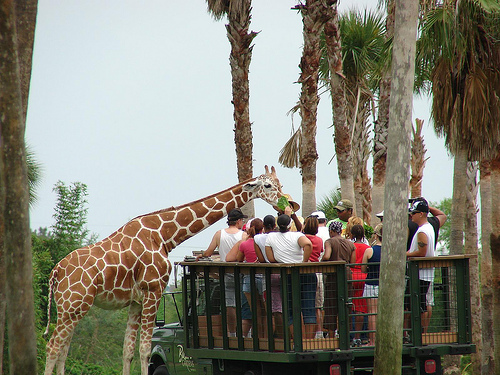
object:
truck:
[149, 288, 476, 373]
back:
[182, 262, 476, 363]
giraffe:
[41, 166, 286, 375]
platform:
[186, 333, 479, 361]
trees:
[214, 2, 262, 373]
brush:
[24, 226, 83, 331]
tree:
[2, 0, 35, 373]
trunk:
[6, 162, 36, 375]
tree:
[343, 5, 385, 235]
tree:
[437, 2, 493, 253]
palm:
[304, 7, 394, 92]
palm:
[416, 2, 499, 92]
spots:
[97, 259, 107, 271]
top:
[248, 164, 279, 181]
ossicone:
[271, 166, 276, 175]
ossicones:
[264, 165, 269, 175]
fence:
[184, 260, 470, 350]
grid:
[301, 268, 458, 350]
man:
[408, 200, 437, 347]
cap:
[408, 198, 429, 212]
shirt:
[265, 231, 307, 264]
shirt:
[216, 226, 245, 261]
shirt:
[254, 233, 274, 263]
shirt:
[410, 224, 437, 283]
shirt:
[312, 226, 335, 260]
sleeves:
[264, 234, 272, 247]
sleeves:
[418, 227, 429, 238]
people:
[194, 208, 248, 340]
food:
[277, 196, 294, 215]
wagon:
[183, 255, 473, 363]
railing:
[176, 253, 477, 270]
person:
[285, 205, 303, 233]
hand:
[285, 206, 292, 217]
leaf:
[275, 196, 288, 211]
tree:
[380, 2, 415, 374]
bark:
[377, 0, 416, 372]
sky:
[29, 0, 459, 280]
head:
[248, 165, 292, 214]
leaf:
[279, 128, 302, 170]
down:
[2, 361, 499, 375]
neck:
[154, 179, 258, 244]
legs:
[137, 289, 159, 373]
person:
[300, 210, 331, 343]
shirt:
[305, 235, 325, 263]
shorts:
[220, 268, 251, 307]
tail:
[43, 271, 53, 336]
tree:
[51, 176, 93, 253]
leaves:
[79, 199, 87, 204]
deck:
[199, 315, 457, 350]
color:
[415, 199, 426, 208]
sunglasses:
[411, 211, 423, 216]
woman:
[345, 227, 375, 345]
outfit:
[348, 242, 370, 312]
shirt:
[239, 235, 262, 265]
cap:
[228, 208, 249, 218]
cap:
[333, 198, 354, 211]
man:
[329, 198, 371, 234]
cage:
[181, 255, 469, 352]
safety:
[185, 249, 473, 357]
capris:
[281, 266, 318, 326]